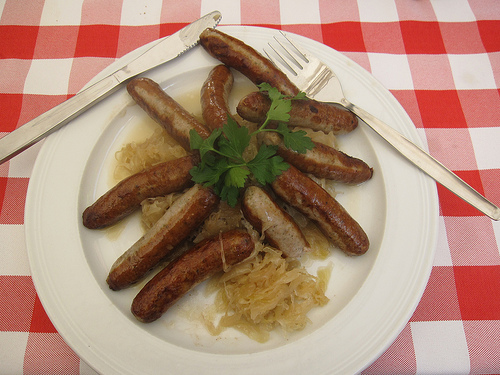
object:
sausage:
[128, 228, 255, 323]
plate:
[23, 24, 439, 374]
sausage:
[107, 181, 221, 292]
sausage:
[82, 154, 198, 231]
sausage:
[127, 75, 209, 152]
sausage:
[200, 64, 239, 129]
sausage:
[199, 28, 302, 98]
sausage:
[237, 93, 359, 132]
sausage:
[257, 128, 374, 185]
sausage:
[273, 164, 371, 256]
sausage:
[241, 185, 312, 263]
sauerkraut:
[110, 127, 332, 342]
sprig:
[227, 148, 290, 186]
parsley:
[187, 83, 310, 209]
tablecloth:
[1, 1, 499, 373]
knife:
[0, 10, 221, 164]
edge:
[179, 15, 222, 58]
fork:
[268, 31, 499, 204]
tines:
[264, 29, 311, 77]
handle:
[345, 103, 499, 221]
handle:
[0, 79, 111, 167]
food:
[119, 78, 324, 303]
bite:
[248, 191, 309, 263]